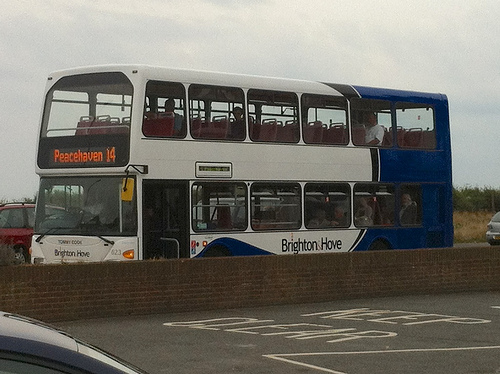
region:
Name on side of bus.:
[274, 237, 348, 252]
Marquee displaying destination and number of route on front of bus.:
[46, 144, 125, 165]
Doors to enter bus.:
[143, 180, 192, 257]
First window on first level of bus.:
[191, 183, 250, 230]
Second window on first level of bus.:
[249, 183, 303, 230]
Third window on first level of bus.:
[304, 183, 352, 229]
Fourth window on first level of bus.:
[353, 183, 395, 225]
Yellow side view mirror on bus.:
[118, 176, 135, 203]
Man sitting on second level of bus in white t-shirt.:
[351, 103, 394, 147]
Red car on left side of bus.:
[1, 199, 31, 249]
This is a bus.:
[18, 63, 466, 265]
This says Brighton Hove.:
[270, 218, 360, 267]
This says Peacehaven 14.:
[36, 126, 130, 183]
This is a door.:
[134, 163, 215, 264]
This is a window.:
[136, 75, 255, 161]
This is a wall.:
[3, 255, 494, 319]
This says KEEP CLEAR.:
[164, 295, 485, 364]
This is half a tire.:
[358, 226, 399, 258]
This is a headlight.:
[117, 240, 142, 263]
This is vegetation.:
[456, 172, 499, 242]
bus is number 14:
[87, 119, 141, 195]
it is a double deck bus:
[33, 68, 453, 253]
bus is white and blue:
[28, 72, 459, 262]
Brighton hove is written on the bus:
[258, 216, 365, 272]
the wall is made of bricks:
[193, 271, 333, 292]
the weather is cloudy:
[264, 48, 345, 74]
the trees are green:
[456, 180, 494, 209]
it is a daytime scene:
[23, 62, 495, 364]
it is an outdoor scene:
[11, 56, 467, 346]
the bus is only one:
[22, 58, 489, 289]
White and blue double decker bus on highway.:
[28, 51, 465, 261]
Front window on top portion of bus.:
[40, 66, 138, 138]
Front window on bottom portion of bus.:
[33, 175, 138, 233]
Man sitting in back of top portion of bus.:
[356, 104, 395, 146]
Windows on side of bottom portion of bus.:
[188, 180, 430, 234]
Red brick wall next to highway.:
[42, 245, 477, 313]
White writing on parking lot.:
[154, 305, 486, 367]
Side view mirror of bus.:
[115, 160, 145, 207]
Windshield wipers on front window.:
[33, 224, 112, 246]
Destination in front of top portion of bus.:
[46, 142, 126, 168]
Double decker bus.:
[21, 61, 456, 253]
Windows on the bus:
[141, 77, 442, 157]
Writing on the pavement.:
[161, 297, 488, 344]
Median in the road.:
[6, 238, 498, 312]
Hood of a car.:
[3, 303, 178, 370]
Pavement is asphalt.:
[129, 328, 271, 371]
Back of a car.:
[479, 209, 499, 244]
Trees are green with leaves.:
[454, 187, 494, 214]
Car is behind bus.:
[4, 195, 34, 258]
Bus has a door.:
[133, 176, 200, 269]